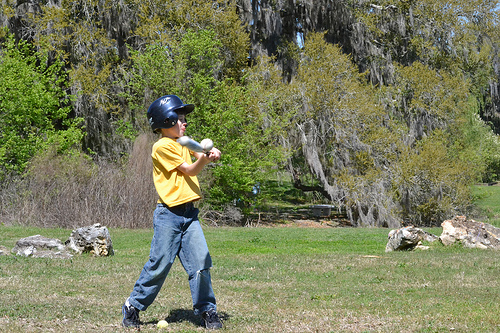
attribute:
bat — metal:
[178, 136, 216, 162]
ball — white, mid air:
[200, 138, 214, 153]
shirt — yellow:
[151, 137, 204, 208]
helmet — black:
[147, 96, 195, 134]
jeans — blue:
[127, 203, 217, 316]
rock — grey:
[71, 223, 114, 256]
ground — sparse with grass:
[0, 226, 499, 333]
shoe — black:
[124, 300, 141, 327]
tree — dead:
[283, 31, 497, 234]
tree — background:
[102, 28, 301, 224]